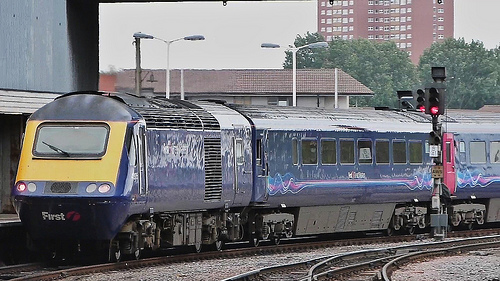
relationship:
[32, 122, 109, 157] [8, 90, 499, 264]
window on train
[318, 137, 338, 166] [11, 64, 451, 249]
window on passenger train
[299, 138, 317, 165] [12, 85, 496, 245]
window on train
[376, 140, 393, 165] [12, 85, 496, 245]
window on passenger train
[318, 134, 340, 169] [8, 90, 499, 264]
window built into train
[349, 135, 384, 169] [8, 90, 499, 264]
window built into train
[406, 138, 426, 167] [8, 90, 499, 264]
window built into train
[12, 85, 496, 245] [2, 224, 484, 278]
train riding on track